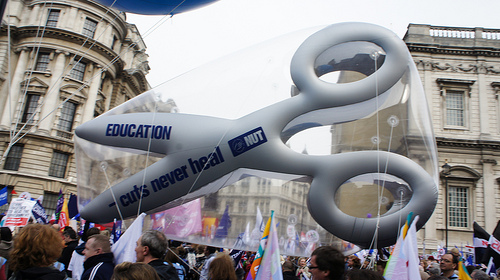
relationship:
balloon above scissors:
[98, 1, 223, 18] [75, 18, 437, 245]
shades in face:
[305, 260, 320, 271] [307, 252, 339, 278]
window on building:
[15, 82, 49, 130] [0, 0, 162, 250]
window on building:
[28, 50, 53, 74] [0, 0, 162, 250]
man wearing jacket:
[73, 235, 114, 278] [77, 251, 116, 278]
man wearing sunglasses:
[290, 243, 347, 278] [307, 260, 325, 270]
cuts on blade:
[119, 183, 160, 225] [86, 159, 208, 236]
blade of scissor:
[86, 159, 208, 236] [79, 2, 430, 264]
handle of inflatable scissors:
[284, 12, 416, 117] [72, 22, 440, 248]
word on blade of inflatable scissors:
[146, 163, 193, 191] [72, 22, 440, 248]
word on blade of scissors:
[187, 145, 227, 179] [78, 140, 240, 227]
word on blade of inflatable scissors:
[187, 145, 227, 179] [72, 22, 440, 248]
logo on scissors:
[223, 122, 272, 164] [75, 18, 437, 245]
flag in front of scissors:
[110, 208, 142, 265] [75, 18, 437, 245]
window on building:
[435, 75, 468, 127] [329, 17, 498, 264]